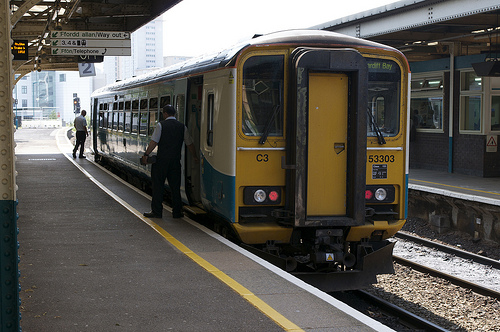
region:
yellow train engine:
[84, 29, 411, 274]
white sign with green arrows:
[48, 29, 128, 61]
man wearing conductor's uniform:
[141, 101, 201, 216]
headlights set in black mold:
[241, 185, 396, 206]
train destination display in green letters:
[361, 52, 396, 75]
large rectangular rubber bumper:
[289, 44, 371, 232]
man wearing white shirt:
[71, 109, 89, 159]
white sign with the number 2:
[77, 61, 96, 77]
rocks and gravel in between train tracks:
[398, 236, 494, 330]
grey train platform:
[15, 154, 96, 303]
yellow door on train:
[300, 63, 357, 223]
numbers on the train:
[365, 151, 395, 161]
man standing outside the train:
[138, 97, 191, 227]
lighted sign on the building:
[11, 37, 33, 71]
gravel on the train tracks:
[383, 274, 465, 314]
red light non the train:
[265, 177, 284, 204]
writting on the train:
[236, 152, 271, 165]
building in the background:
[18, 11, 193, 106]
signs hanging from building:
[52, 26, 145, 63]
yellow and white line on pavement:
[213, 257, 330, 329]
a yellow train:
[83, 23, 445, 295]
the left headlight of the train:
[242, 175, 302, 220]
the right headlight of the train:
[358, 175, 408, 214]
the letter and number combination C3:
[252, 143, 287, 171]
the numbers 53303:
[363, 145, 417, 172]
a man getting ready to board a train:
[139, 95, 216, 230]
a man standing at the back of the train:
[68, 103, 93, 168]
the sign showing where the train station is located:
[48, 22, 142, 63]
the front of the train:
[225, 17, 445, 245]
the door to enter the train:
[172, 65, 217, 234]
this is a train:
[232, 46, 414, 191]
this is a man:
[139, 105, 189, 212]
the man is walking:
[68, 110, 93, 155]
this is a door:
[188, 79, 201, 209]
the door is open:
[184, 84, 206, 194]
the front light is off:
[253, 187, 286, 204]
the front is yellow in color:
[319, 104, 346, 202]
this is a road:
[90, 233, 145, 291]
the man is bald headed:
[168, 100, 175, 112]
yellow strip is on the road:
[266, 300, 292, 320]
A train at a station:
[68, 67, 463, 304]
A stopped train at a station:
[57, 79, 414, 285]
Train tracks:
[248, 179, 472, 330]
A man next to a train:
[119, 100, 215, 242]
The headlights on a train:
[238, 174, 404, 222]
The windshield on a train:
[213, 43, 413, 154]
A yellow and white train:
[121, 43, 426, 270]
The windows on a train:
[75, 83, 216, 161]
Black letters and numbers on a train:
[239, 141, 407, 175]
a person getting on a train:
[49, 91, 109, 178]